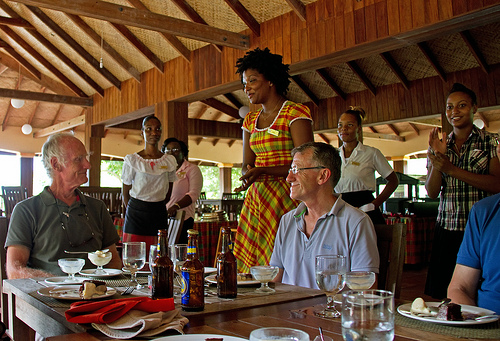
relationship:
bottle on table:
[183, 228, 205, 309] [7, 264, 499, 340]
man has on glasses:
[270, 142, 377, 291] [289, 166, 328, 173]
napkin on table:
[66, 296, 175, 323] [7, 264, 499, 340]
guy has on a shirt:
[4, 132, 122, 282] [4, 185, 121, 272]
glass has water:
[123, 240, 145, 288] [123, 258, 147, 271]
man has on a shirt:
[270, 142, 377, 291] [269, 195, 382, 290]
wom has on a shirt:
[425, 82, 499, 300] [428, 124, 500, 230]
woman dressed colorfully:
[425, 82, 499, 301] [428, 124, 498, 230]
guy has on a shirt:
[5, 185, 120, 276] [4, 185, 121, 272]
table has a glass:
[7, 264, 499, 340] [123, 240, 145, 288]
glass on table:
[123, 240, 145, 288] [7, 264, 499, 340]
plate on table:
[398, 301, 498, 326] [7, 264, 499, 340]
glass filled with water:
[123, 240, 145, 288] [123, 258, 147, 271]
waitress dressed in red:
[232, 47, 316, 277] [293, 105, 313, 117]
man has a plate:
[270, 142, 377, 291] [398, 301, 498, 326]